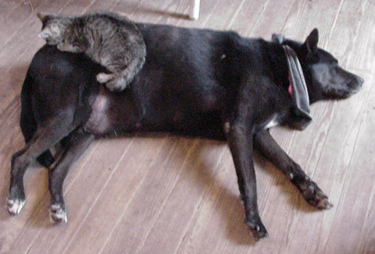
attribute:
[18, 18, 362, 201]
large — lazy, black, laying, asleep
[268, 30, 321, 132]
bandana — grey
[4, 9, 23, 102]
floor — brown, wooden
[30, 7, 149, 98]
cat — lazy, black, gray, cute, curled, striped, asleep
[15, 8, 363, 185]
dog — black